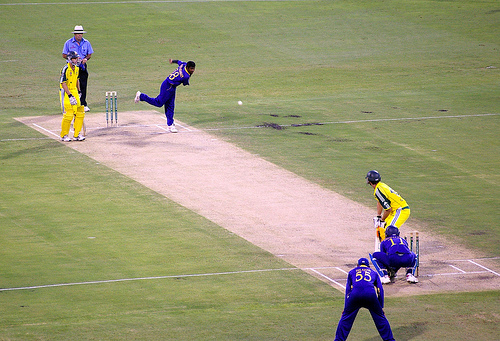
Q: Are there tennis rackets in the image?
A: No, there are no tennis rackets.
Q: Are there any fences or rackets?
A: No, there are no rackets or fences.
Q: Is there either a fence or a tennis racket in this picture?
A: No, there are no rackets or fences.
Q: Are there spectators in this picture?
A: No, there are no spectators.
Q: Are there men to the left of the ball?
A: Yes, there is a man to the left of the ball.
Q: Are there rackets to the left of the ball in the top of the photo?
A: No, there is a man to the left of the ball.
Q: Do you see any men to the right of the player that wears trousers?
A: Yes, there is a man to the right of the player.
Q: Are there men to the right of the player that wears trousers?
A: Yes, there is a man to the right of the player.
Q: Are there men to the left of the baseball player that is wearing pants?
A: No, the man is to the right of the player.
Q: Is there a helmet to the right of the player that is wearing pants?
A: No, there is a man to the right of the player.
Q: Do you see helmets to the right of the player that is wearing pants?
A: No, there is a man to the right of the player.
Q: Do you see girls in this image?
A: No, there are no girls.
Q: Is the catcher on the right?
A: Yes, the catcher is on the right of the image.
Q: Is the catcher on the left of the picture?
A: No, the catcher is on the right of the image.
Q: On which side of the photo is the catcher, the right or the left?
A: The catcher is on the right of the image.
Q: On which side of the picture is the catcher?
A: The catcher is on the right of the image.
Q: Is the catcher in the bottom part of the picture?
A: Yes, the catcher is in the bottom of the image.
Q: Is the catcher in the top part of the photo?
A: No, the catcher is in the bottom of the image.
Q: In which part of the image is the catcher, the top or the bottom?
A: The catcher is in the bottom of the image.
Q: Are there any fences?
A: No, there are no fences.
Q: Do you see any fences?
A: No, there are no fences.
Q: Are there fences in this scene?
A: No, there are no fences.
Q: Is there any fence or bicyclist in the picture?
A: No, there are no fences or cyclists.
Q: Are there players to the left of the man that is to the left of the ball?
A: Yes, there is a player to the left of the man.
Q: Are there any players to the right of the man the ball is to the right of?
A: No, the player is to the left of the man.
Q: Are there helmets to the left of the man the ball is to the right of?
A: No, there is a player to the left of the man.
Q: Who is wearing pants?
A: The player is wearing pants.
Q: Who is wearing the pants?
A: The player is wearing pants.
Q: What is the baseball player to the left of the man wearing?
A: The player is wearing pants.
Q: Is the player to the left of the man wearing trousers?
A: Yes, the player is wearing trousers.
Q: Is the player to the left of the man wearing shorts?
A: No, the player is wearing trousers.